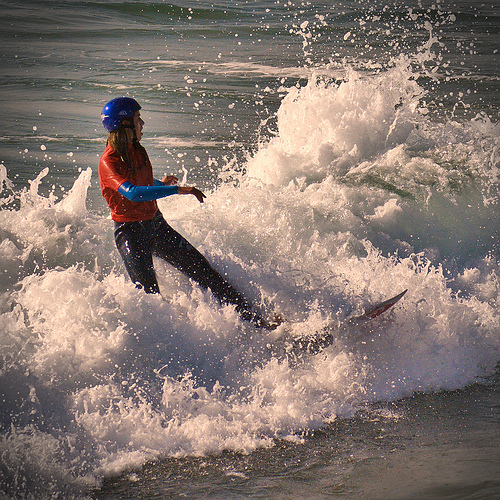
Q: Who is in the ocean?
A: A woman.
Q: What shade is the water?
A: White.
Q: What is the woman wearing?
A: A wetsuit.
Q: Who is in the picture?
A: A girl.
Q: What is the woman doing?
A: Surfing.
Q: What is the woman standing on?
A: Surfboard.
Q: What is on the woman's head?
A: Helmet.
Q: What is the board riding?
A: Wave.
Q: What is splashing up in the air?
A: Water.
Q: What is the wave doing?
A: Crashing.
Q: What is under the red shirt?
A: Blue shirt.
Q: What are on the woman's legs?
A: Wet pants.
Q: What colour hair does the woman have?
A: Brown.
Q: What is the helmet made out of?
A: Plastic.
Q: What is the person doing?
A: Surfing.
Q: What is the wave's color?
A: White.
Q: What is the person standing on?
A: Surfboard.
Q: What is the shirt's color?
A: Red.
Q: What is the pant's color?
A: Black.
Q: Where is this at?
A: Ocean.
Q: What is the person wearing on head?
A: Helmet.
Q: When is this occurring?
A: During the day time.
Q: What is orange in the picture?
A: The woman's shirt.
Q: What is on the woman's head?
A: A blue helmet.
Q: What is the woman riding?
A: A wave.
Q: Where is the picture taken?
A: An ocean.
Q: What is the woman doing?
A: Surfing.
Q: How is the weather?
A: Sunny.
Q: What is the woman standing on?
A: A surfboard.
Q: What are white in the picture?
A: Waves.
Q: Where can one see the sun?
A: The waves.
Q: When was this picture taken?
A: During the day.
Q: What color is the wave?
A: White.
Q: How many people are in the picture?
A: One.